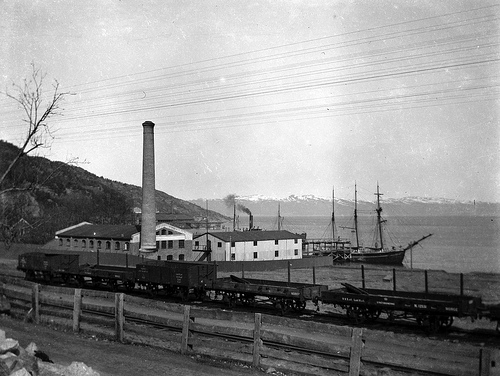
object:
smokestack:
[139, 120, 157, 260]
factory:
[44, 120, 334, 273]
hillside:
[0, 138, 236, 246]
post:
[32, 283, 40, 326]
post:
[72, 288, 81, 333]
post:
[114, 293, 124, 343]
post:
[181, 304, 190, 355]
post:
[252, 313, 261, 375]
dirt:
[13, 328, 161, 374]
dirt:
[320, 265, 499, 297]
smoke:
[222, 194, 252, 216]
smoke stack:
[248, 215, 254, 229]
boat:
[311, 183, 353, 266]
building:
[138, 119, 158, 251]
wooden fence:
[0, 274, 497, 374]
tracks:
[13, 267, 480, 340]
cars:
[211, 274, 328, 316]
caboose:
[17, 252, 218, 301]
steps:
[187, 238, 215, 260]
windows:
[231, 242, 236, 248]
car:
[16, 249, 80, 283]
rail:
[0, 267, 27, 280]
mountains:
[196, 192, 498, 219]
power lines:
[17, 57, 500, 124]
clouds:
[251, 117, 446, 177]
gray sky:
[171, 78, 474, 180]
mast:
[354, 179, 361, 248]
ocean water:
[245, 218, 498, 275]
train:
[16, 249, 500, 348]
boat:
[350, 180, 435, 265]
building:
[191, 224, 306, 261]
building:
[54, 213, 194, 264]